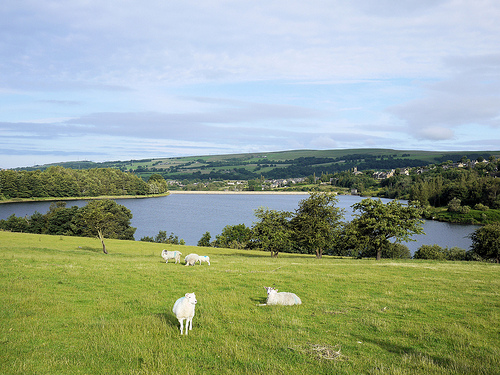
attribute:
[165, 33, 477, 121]
clouds — thin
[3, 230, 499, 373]
grass — short, green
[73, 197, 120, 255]
tree — bent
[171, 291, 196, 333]
lamb — white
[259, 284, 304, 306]
lamb — lying